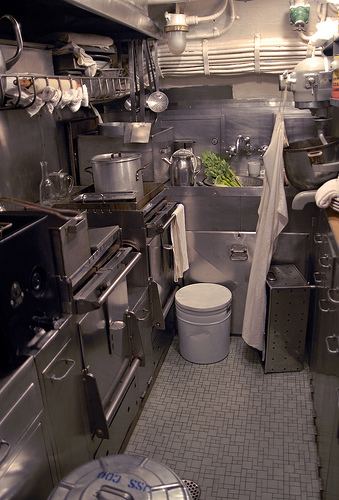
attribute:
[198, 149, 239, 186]
leaves — green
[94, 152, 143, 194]
pot — silver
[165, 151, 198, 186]
jug — silver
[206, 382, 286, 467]
floor — tiled, grey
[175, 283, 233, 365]
pail — white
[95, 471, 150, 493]
writing — blue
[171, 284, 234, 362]
container — cylindrical, white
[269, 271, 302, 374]
box — silver, metal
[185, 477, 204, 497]
drain — silver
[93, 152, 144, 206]
pot — silver, large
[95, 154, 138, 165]
pot lid — large, silver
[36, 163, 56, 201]
container — long-neck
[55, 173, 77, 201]
pitcher — clear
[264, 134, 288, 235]
apron — long, white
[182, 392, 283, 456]
linoleum — squared, gray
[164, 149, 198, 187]
pitcher — silver, metal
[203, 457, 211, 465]
tile — white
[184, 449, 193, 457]
tile — white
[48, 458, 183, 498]
lid — metal can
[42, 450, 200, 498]
can — trash, metal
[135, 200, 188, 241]
cabinets — metal handles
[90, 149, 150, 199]
pot — covered 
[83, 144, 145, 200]
pot — covered 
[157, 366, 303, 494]
floor — Tile cover kitchen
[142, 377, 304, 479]
floor — patterned tile covered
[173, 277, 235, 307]
cover —  safety, light 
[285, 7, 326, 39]
cover — safety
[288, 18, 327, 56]
light — electric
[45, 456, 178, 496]
lid — trash can 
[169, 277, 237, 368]
pail — five gallon white 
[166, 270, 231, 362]
pail — large white, closed lid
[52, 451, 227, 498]
cover — silver metal trash can 